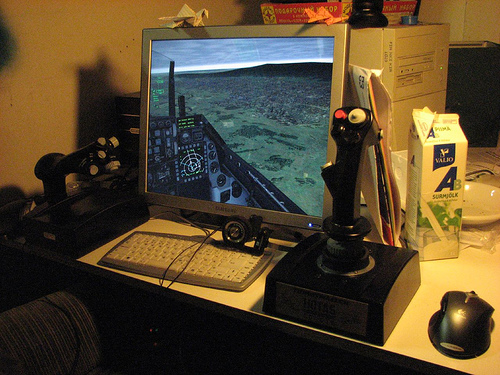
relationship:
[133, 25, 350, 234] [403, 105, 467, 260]
computer monitor on top of 2. container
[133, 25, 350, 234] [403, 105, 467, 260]
computer monitor on 2. container